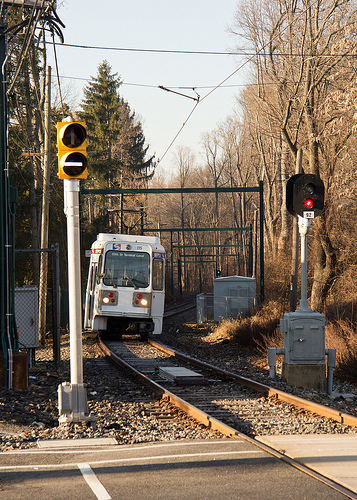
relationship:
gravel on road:
[18, 318, 298, 437] [0, 396, 355, 494]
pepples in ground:
[134, 418, 156, 437] [15, 366, 320, 425]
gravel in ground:
[0, 307, 357, 453] [12, 407, 226, 443]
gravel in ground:
[0, 307, 357, 453] [4, 305, 355, 448]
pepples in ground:
[0, 331, 357, 451] [29, 325, 332, 432]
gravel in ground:
[0, 307, 357, 453] [29, 331, 340, 436]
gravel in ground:
[0, 307, 357, 453] [20, 305, 325, 424]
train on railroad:
[77, 231, 165, 337] [95, 296, 357, 500]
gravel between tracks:
[0, 307, 357, 453] [115, 331, 343, 438]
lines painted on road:
[76, 464, 111, 499] [0, 435, 356, 497]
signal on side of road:
[52, 118, 95, 180] [20, 431, 348, 497]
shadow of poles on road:
[79, 458, 166, 480] [183, 466, 246, 494]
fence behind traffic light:
[7, 227, 73, 357] [52, 97, 94, 427]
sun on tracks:
[122, 334, 176, 360] [96, 337, 356, 499]